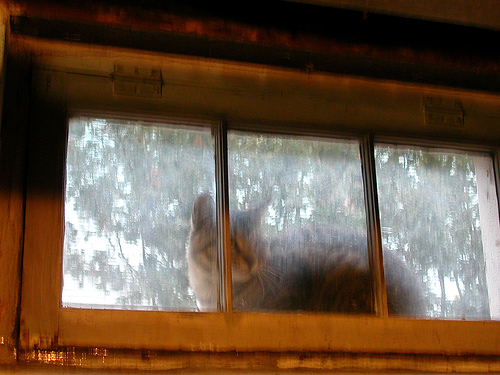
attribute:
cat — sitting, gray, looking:
[166, 186, 311, 285]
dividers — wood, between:
[191, 118, 260, 311]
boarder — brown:
[160, 23, 415, 109]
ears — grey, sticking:
[183, 187, 224, 228]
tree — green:
[248, 143, 363, 220]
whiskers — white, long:
[208, 254, 271, 294]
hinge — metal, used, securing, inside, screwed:
[344, 92, 475, 124]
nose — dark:
[235, 243, 264, 265]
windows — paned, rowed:
[66, 104, 475, 319]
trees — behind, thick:
[255, 145, 367, 218]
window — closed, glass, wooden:
[69, 90, 302, 327]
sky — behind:
[82, 221, 135, 260]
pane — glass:
[110, 135, 219, 279]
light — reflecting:
[90, 148, 153, 293]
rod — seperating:
[336, 136, 406, 318]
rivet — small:
[86, 64, 150, 96]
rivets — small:
[100, 44, 480, 131]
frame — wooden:
[148, 306, 453, 359]